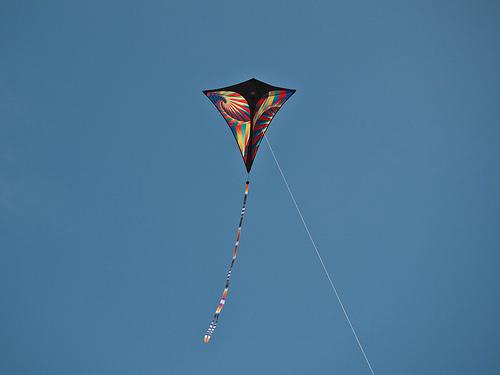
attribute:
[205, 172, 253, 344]
tail — kite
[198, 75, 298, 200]
kite — black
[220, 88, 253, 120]
spiral shape — colored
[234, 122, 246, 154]
stripe — Orange , green 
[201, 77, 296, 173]
diamond shape — black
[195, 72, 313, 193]
kite — white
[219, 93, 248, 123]
print — colored